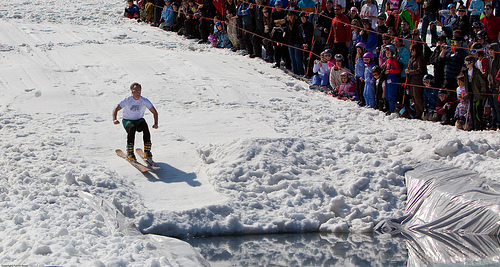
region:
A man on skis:
[103, 69, 198, 179]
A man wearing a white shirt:
[120, 75, 167, 144]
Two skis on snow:
[116, 149, 164, 178]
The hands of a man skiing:
[105, 115, 163, 130]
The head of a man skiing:
[126, 75, 151, 102]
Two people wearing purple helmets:
[353, 38, 378, 101]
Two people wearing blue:
[346, 35, 377, 97]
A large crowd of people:
[265, 15, 483, 114]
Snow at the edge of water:
[150, 195, 390, 249]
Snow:
[37, 195, 100, 251]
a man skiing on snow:
[109, 80, 162, 176]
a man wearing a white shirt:
[109, 81, 161, 175]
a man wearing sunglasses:
[113, 82, 163, 179]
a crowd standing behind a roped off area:
[122, 1, 499, 134]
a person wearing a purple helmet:
[361, 51, 376, 110]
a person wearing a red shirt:
[382, 46, 400, 113]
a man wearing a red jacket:
[324, 3, 352, 68]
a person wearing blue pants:
[379, 43, 399, 117]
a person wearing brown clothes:
[406, 41, 426, 120]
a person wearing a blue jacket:
[354, 18, 379, 60]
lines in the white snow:
[31, 34, 133, 65]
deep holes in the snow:
[245, 150, 369, 247]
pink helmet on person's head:
[357, 46, 374, 63]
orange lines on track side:
[210, 11, 442, 101]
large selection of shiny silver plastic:
[390, 158, 474, 265]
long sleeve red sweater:
[380, 58, 401, 75]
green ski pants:
[115, 112, 162, 148]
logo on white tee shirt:
[125, 100, 160, 125]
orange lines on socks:
[121, 136, 171, 151]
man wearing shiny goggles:
[121, 85, 180, 104]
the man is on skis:
[110, 80, 164, 179]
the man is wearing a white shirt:
[110, 93, 155, 118]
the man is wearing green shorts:
[121, 113, 151, 133]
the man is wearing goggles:
[130, 86, 142, 96]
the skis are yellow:
[111, 146, 162, 177]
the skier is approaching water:
[106, 82, 168, 177]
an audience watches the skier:
[123, 0, 498, 134]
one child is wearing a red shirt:
[382, 57, 400, 77]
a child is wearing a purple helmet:
[362, 51, 375, 63]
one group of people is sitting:
[307, 46, 354, 100]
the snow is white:
[23, 45, 105, 132]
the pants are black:
[112, 115, 164, 163]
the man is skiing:
[101, 67, 185, 199]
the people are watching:
[299, 14, 480, 102]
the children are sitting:
[300, 46, 372, 111]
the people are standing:
[416, 22, 476, 69]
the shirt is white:
[107, 76, 167, 126]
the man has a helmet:
[104, 71, 154, 127]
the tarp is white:
[409, 155, 490, 247]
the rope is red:
[377, 20, 427, 95]